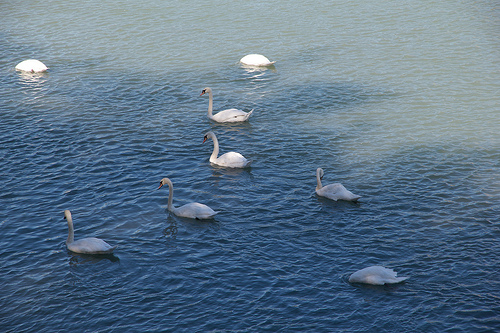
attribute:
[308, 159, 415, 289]
swans — right-most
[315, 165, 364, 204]
bird — gray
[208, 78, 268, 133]
duck — white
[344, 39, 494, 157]
water — partially-shaded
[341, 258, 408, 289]
ducks — wavy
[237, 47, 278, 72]
swan — top-most, white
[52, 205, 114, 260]
swan — right bottom, shadowed-over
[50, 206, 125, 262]
bird — gray, swimming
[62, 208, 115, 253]
bird — grey, swimming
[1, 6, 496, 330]
water — calm, blue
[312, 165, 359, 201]
bird — grey, swimming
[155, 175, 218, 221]
bird — gray, grey, swimming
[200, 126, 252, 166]
bird — grey, swimming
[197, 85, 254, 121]
bird — grey, swimming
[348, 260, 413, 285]
bird — gray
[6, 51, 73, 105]
swan — white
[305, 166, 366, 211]
swan — middle, shadowed-over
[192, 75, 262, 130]
swan — middle, shadowed-over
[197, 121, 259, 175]
swan — middle, shadowed-over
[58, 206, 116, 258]
bird — blue